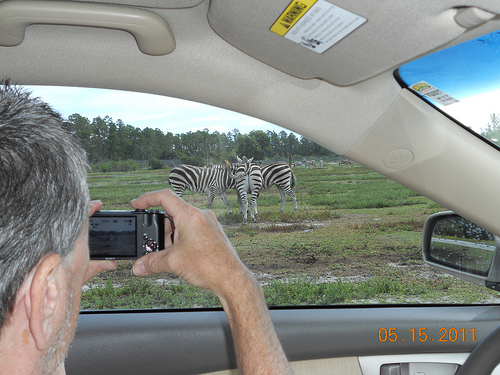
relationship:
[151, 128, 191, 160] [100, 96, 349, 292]
tree in distance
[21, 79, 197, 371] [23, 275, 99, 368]
man has bear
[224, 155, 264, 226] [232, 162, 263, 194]
animal has tail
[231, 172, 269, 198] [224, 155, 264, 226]
animal behind animal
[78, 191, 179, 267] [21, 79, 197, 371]
camera in man